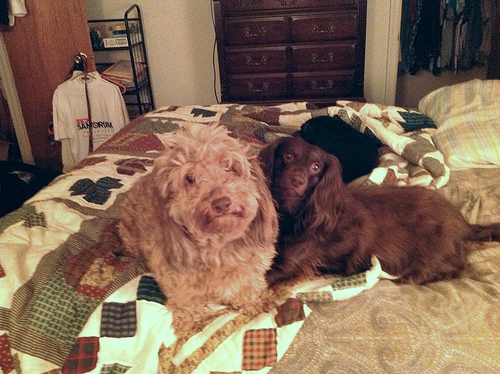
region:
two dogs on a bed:
[149, 162, 479, 310]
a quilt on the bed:
[33, 115, 162, 232]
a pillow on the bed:
[427, 76, 499, 185]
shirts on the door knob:
[65, 53, 130, 160]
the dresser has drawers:
[222, 9, 387, 94]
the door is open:
[3, 22, 119, 92]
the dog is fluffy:
[148, 127, 275, 328]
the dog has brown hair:
[271, 141, 496, 286]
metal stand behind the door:
[105, 3, 191, 125]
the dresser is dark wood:
[253, 11, 367, 81]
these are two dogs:
[118, 130, 486, 299]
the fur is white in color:
[191, 245, 243, 276]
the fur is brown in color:
[349, 192, 419, 247]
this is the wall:
[156, 27, 191, 72]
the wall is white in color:
[148, 14, 208, 58]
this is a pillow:
[426, 75, 498, 160]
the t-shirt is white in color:
[58, 92, 78, 124]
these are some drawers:
[217, 2, 367, 97]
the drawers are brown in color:
[278, 17, 295, 64]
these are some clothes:
[413, 7, 499, 55]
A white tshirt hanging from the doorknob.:
[53, 82, 122, 159]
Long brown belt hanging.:
[78, 52, 98, 151]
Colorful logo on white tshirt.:
[72, 112, 119, 134]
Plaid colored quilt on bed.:
[69, 173, 99, 276]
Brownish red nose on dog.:
[199, 190, 243, 221]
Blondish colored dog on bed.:
[102, 112, 276, 317]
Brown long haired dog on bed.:
[258, 130, 495, 292]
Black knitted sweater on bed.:
[306, 113, 393, 152]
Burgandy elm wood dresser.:
[214, 43, 371, 95]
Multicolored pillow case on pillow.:
[419, 75, 497, 170]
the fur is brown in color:
[323, 200, 430, 262]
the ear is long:
[319, 165, 346, 220]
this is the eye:
[309, 157, 324, 171]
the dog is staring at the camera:
[274, 150, 329, 196]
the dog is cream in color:
[120, 143, 269, 299]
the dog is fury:
[179, 220, 265, 296]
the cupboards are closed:
[232, 12, 344, 102]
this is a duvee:
[352, 302, 446, 372]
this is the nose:
[212, 197, 233, 209]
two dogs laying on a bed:
[118, 125, 490, 311]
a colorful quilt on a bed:
[0, 157, 127, 352]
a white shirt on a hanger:
[57, 50, 129, 147]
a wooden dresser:
[208, 3, 369, 100]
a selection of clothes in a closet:
[406, 2, 499, 79]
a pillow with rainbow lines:
[436, 71, 499, 179]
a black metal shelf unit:
[98, 7, 175, 109]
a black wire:
[203, 2, 225, 102]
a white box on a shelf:
[101, 16, 136, 51]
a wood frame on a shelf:
[102, 56, 149, 79]